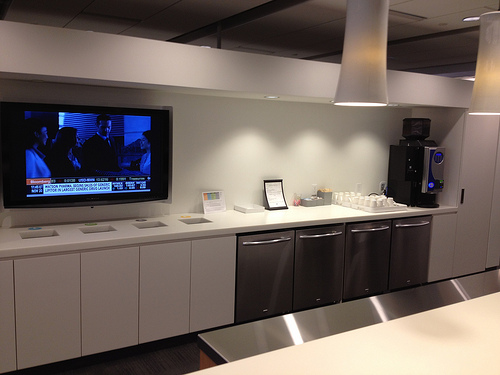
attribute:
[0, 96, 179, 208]
border — black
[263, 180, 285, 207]
paper — framed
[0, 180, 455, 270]
counter — white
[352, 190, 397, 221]
cups — white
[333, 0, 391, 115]
lamp — white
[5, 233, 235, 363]
cabinets — white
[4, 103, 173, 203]
television — on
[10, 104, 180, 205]
tv — on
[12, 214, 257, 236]
holes — four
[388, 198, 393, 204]
cups — white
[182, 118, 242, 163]
wall — white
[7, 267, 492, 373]
kitchen — lounge area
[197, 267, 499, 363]
counter top — silver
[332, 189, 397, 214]
cups — white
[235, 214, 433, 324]
cabinets — metal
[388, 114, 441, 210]
machine — large, coffee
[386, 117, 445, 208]
beverage dispenser — black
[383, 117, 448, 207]
beverage machine — black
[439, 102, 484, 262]
door — white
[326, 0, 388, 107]
light — round, hanging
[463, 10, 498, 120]
light — hanging, round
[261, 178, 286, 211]
frame — black